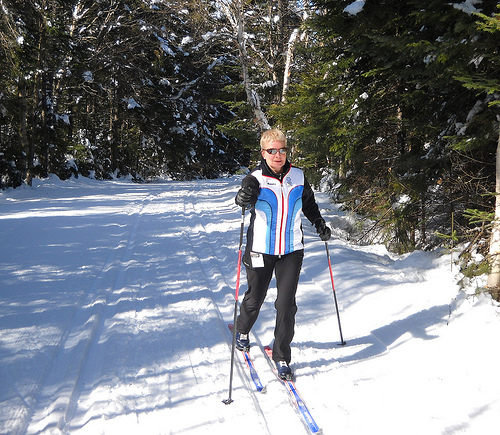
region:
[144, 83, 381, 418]
the woman is skiing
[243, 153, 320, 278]
the coat is white in colour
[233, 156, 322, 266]
it has blue and red stripes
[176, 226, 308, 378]
the pant is black in colour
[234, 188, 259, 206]
the gloves are black in colour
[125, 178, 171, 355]
the snow is white in colour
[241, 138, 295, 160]
the lady has goggles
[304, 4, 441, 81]
the trees are covered by snow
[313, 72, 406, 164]
the trees are green in colour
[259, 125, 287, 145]
the hair is brown in colour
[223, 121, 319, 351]
this is a lady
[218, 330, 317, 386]
these are the skiis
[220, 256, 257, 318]
this is a stick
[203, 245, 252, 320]
the stick is thin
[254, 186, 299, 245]
this is a jacket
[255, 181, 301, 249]
the jacket is white in color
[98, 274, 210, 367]
the place is full of snow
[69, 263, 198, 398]
the snow is white in color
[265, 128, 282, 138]
this is the hair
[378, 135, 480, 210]
these are the leaves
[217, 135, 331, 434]
woman skiing through the snow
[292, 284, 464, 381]
woman's shadow on the snow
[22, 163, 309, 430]
two sets of tracks in the snow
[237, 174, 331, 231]
black sleeves of woman's jacket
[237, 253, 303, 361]
black pants skier is wearing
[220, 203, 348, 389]
red and black ski poles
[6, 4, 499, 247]
trees lining the path in the snow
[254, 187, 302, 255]
blue stripes on the jacket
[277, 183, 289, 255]
red zipper on the jacket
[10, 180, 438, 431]
path skier is traveling on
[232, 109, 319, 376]
MAN WALKING ON SKI SLOPE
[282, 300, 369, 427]
BLUE SKI UNDER MAN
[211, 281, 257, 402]
BLUE SKI UNDER MAN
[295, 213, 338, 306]
BLACK AND RED POLE IN HAND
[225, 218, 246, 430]
BLACK AND RED POLE IN HAND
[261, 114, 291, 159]
BLONDE HAIR IN SKIER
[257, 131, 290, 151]
SUNGLASSES ON MAN'S FACE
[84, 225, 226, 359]
SHADOWS OF TREES ON SNOW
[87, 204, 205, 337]
SKI TRACKS IN SNOW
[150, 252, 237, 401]
WHITE SNOW BETWEEN TREES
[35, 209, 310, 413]
Ground is white color.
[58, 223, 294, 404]
Snow is in ground.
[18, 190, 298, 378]
Shadow is in ground.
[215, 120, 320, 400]
One woman is skiing.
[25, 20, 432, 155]
Trees are green color.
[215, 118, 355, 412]
Woman is holding ski poles in hand.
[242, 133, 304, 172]
Woman is wearing eye glass.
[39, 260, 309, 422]
Marks on snow.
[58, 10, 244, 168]
Snow on trees.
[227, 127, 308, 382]
Woman is wearing black pant.